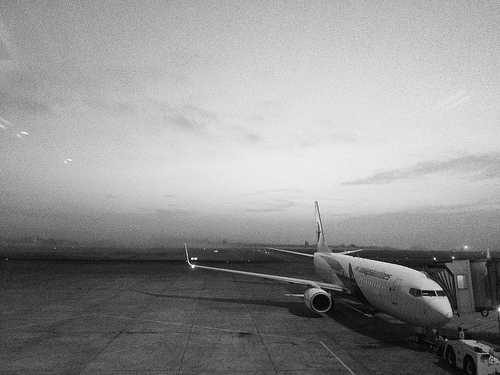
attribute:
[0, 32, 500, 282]
sky — daytime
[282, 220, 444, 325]
plane — parked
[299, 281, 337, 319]
engine — jet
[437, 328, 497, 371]
vehicle — for luggage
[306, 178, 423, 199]
cloud — large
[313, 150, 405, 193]
cloud — large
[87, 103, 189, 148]
cloud — large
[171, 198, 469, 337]
airplane — large, white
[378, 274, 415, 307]
door — large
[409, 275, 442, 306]
window — small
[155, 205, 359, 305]
sidewing — large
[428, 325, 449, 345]
people — sitting